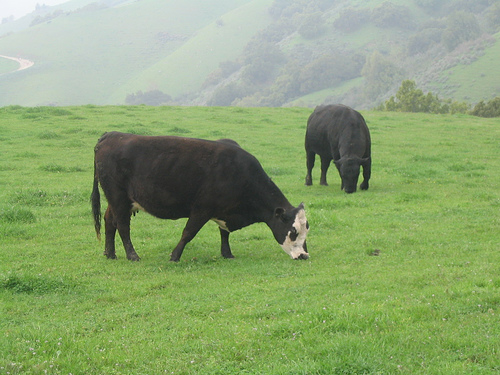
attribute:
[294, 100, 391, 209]
cow — eating, black, healthy, healty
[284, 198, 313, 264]
face — white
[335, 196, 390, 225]
grass — lush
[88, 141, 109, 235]
tail — hairy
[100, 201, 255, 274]
legs — black